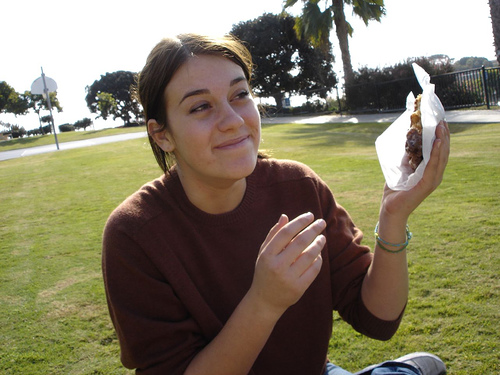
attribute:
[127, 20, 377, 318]
girl — smiling, eating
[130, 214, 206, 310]
sweater — burgundy, dark, brown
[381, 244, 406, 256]
bracelet — green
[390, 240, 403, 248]
bracelet — blue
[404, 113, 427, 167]
food — yummy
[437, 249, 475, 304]
grass — well groomed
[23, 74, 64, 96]
hoop — white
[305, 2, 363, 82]
palm tree — tall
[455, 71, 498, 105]
fence — black, iron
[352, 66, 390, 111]
tree — short, bushy, full, large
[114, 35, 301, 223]
woman — smiling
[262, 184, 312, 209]
shirt — brown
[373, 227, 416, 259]
bracelets — green, blue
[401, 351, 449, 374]
shoe — white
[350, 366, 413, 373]
jeans — blue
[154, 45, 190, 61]
hair — brown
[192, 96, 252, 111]
eyes — dark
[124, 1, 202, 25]
sky — clear, blue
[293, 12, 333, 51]
leaves — green